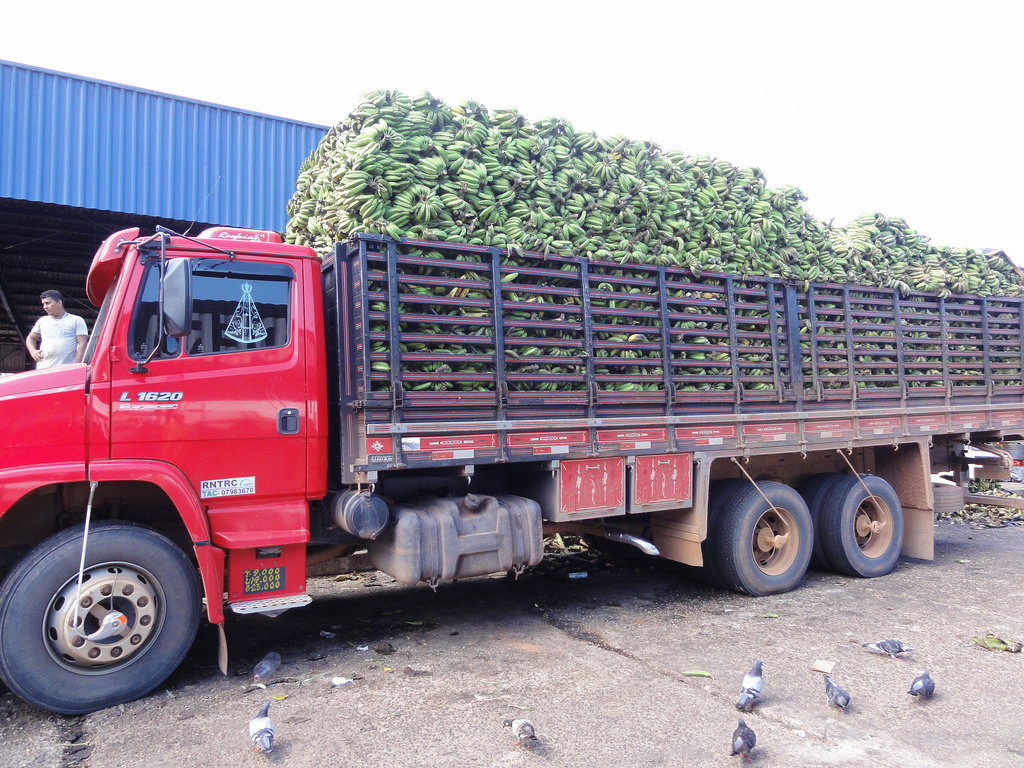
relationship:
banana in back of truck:
[441, 146, 537, 239] [1, 81, 1021, 717]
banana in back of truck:
[614, 293, 700, 382] [1, 81, 1021, 717]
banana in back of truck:
[729, 310, 816, 355] [1, 81, 1021, 717]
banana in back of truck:
[899, 241, 938, 293] [1, 81, 1021, 717]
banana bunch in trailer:
[405, 148, 451, 192] [273, 75, 1014, 423]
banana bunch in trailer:
[348, 185, 390, 227] [273, 75, 1014, 423]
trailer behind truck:
[329, 225, 1020, 602] [5, 213, 1023, 713]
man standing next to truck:
[25, 289, 88, 381] [5, 213, 1023, 713]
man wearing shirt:
[22, 281, 95, 380] [31, 307, 88, 371]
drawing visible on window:
[221, 276, 266, 344] [133, 256, 292, 365]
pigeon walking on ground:
[724, 714, 763, 766] [3, 438, 1022, 759]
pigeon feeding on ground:
[484, 709, 552, 760] [3, 438, 1022, 759]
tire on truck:
[0, 520, 198, 723] [5, 213, 1023, 713]